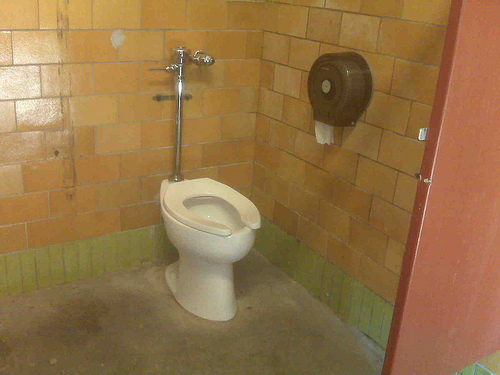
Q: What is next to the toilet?
A: Toilet dispenser.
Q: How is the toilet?
A: Clean.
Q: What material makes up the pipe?
A: Silver.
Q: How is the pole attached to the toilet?
A: It's connected to the wall.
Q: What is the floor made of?
A: Cement.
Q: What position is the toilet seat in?
A: The toilet seat is down.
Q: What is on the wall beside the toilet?
A: A toilet paper dispenser.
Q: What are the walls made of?
A: Tan bricks.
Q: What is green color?
A: Wall.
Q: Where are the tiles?
A: On wall.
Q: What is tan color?
A: Wall.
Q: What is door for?
A: Stall.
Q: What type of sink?
A: Toilet.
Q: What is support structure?
A: Wall.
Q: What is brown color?
A: Wall.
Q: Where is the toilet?
A: In corner.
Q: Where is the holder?
A: On wall.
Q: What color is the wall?
A: Yellow.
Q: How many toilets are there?
A: One.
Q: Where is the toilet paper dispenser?
A: On the wall.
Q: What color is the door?
A: Brown.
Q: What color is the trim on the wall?
A: Green.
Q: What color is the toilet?
A: White.